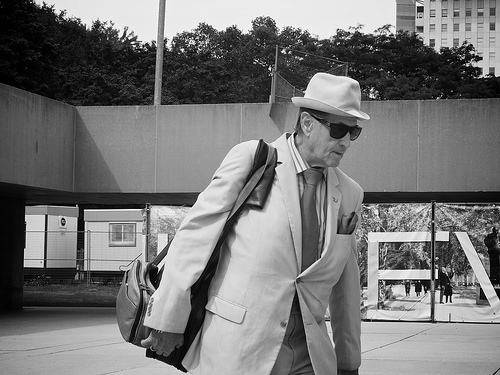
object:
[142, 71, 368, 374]
man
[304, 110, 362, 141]
sunglasses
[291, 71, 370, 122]
hat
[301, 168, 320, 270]
tie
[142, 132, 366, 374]
suit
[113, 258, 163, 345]
bag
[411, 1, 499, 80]
building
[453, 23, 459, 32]
windows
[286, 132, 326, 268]
shirt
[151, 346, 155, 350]
ring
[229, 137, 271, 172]
shoulder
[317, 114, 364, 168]
face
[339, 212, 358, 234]
tissue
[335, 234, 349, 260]
pocket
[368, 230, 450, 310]
letters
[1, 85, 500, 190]
wall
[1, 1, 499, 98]
background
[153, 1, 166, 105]
pole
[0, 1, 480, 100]
tops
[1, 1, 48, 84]
trees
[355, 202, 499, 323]
window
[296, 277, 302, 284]
buttons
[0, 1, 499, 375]
photo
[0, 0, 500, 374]
day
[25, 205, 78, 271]
trailers